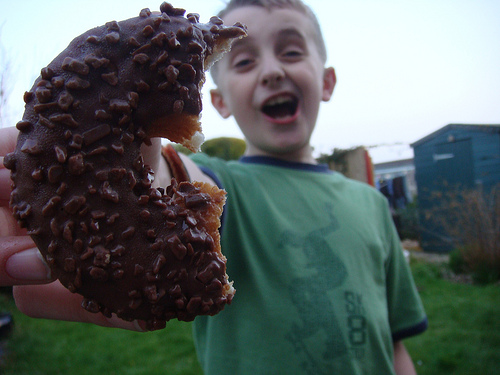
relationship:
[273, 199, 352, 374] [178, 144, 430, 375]
design on top of shirt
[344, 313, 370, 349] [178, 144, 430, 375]
number on top of shirt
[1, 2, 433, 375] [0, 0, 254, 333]
boy holding doughnut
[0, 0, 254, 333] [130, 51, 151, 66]
doughnut has sprinkle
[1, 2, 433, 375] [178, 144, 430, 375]
boy wearing shirt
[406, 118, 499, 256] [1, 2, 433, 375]
shed behind boy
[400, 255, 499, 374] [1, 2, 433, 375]
grass behind boy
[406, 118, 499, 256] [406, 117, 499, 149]
shed has roof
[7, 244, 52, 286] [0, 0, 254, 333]
fingernail next to doughnut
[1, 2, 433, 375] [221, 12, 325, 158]
boy has face